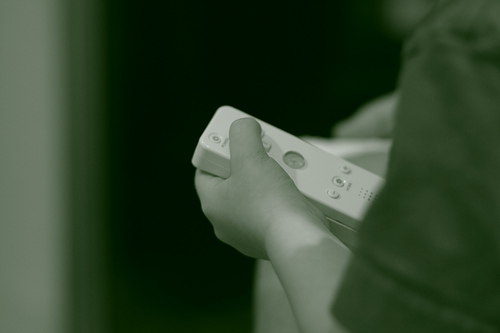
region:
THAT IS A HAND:
[199, 137, 345, 332]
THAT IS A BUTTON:
[288, 147, 305, 172]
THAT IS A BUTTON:
[324, 187, 344, 202]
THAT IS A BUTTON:
[335, 172, 347, 190]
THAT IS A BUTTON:
[336, 167, 353, 179]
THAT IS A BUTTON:
[209, 127, 224, 150]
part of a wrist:
[295, 225, 330, 264]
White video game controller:
[191, 93, 386, 260]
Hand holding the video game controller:
[186, 112, 350, 329]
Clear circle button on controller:
[278, 144, 308, 171]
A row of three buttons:
[328, 157, 353, 206]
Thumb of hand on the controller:
[225, 111, 269, 166]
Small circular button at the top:
[206, 127, 220, 143]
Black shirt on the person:
[326, 0, 498, 327]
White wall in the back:
[0, 0, 71, 330]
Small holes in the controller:
[356, 182, 376, 207]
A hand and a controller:
[180, 92, 384, 276]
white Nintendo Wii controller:
[198, 106, 412, 216]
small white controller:
[196, 103, 403, 218]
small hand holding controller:
[186, 118, 331, 245]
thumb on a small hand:
[219, 113, 276, 170]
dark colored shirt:
[374, 30, 477, 297]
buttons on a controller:
[204, 108, 373, 207]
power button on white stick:
[203, 131, 234, 151]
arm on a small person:
[194, 116, 380, 319]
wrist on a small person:
[202, 118, 361, 319]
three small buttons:
[328, 158, 350, 199]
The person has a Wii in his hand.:
[187, 93, 399, 250]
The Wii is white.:
[194, 100, 326, 197]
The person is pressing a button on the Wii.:
[220, 113, 275, 177]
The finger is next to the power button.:
[198, 108, 271, 170]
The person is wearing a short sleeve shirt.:
[311, 4, 491, 331]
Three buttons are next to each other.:
[316, 160, 360, 205]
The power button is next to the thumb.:
[199, 116, 268, 161]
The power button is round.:
[200, 121, 231, 161]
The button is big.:
[277, 146, 311, 178]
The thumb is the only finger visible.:
[190, 99, 297, 239]